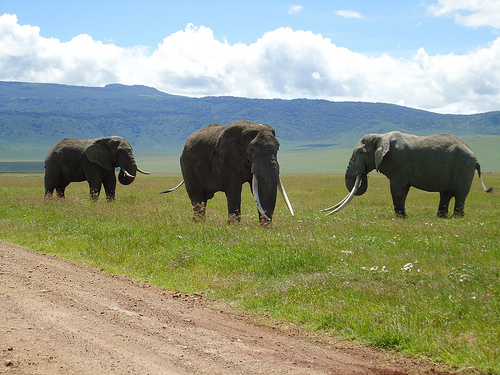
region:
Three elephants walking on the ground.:
[43, 120, 495, 225]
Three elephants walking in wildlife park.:
[41, 118, 491, 223]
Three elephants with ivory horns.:
[43, 115, 494, 225]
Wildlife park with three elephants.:
[0, 80, 498, 372]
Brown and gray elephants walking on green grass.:
[42, 120, 495, 253]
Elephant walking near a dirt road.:
[156, 120, 294, 374]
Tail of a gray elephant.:
[475, 154, 495, 203]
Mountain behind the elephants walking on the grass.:
[4, 80, 498, 229]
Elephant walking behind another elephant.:
[42, 136, 149, 203]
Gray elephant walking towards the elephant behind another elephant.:
[320, 132, 492, 222]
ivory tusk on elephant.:
[242, 181, 261, 231]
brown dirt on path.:
[47, 297, 137, 352]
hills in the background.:
[138, 95, 333, 119]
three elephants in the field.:
[25, 132, 468, 189]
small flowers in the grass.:
[348, 258, 479, 293]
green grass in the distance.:
[290, 151, 336, 169]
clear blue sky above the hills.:
[69, 7, 161, 24]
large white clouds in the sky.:
[277, 45, 339, 77]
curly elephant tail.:
[480, 167, 493, 202]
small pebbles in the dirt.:
[20, 264, 112, 324]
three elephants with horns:
[26, 82, 484, 214]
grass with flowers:
[234, 209, 456, 299]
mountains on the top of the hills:
[6, 67, 337, 125]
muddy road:
[21, 232, 261, 346]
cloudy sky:
[88, 15, 465, 107]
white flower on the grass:
[396, 247, 462, 311]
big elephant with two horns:
[174, 100, 296, 249]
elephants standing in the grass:
[22, 90, 499, 254]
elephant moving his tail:
[335, 97, 496, 242]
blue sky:
[52, 0, 344, 36]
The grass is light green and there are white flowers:
[358, 260, 444, 353]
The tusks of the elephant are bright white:
[326, 180, 363, 222]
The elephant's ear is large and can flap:
[371, 133, 393, 174]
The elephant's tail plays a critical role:
[471, 167, 498, 207]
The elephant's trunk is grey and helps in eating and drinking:
[120, 167, 145, 194]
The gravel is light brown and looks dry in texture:
[105, 311, 175, 364]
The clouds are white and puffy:
[283, 40, 345, 79]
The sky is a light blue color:
[371, 15, 401, 46]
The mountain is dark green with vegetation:
[136, 96, 205, 126]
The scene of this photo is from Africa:
[41, 6, 422, 348]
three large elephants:
[40, 110, 472, 240]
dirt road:
[2, 243, 264, 369]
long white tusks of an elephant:
[246, 164, 303, 229]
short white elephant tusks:
[108, 139, 158, 206]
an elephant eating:
[340, 118, 405, 246]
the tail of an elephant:
[459, 136, 494, 196]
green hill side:
[45, 78, 360, 169]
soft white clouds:
[250, 23, 456, 83]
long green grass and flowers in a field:
[273, 240, 454, 306]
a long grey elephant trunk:
[248, 155, 291, 237]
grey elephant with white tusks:
[157, 107, 302, 238]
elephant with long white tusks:
[319, 119, 496, 237]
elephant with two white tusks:
[32, 130, 158, 207]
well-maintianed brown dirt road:
[0, 216, 482, 371]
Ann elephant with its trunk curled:
[43, 135, 149, 201]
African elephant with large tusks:
[160, 120, 295, 226]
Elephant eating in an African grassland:
[320, 130, 494, 217]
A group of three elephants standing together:
[44, 119, 490, 225]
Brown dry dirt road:
[1, 239, 454, 374]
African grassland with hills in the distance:
[1, 81, 498, 373]